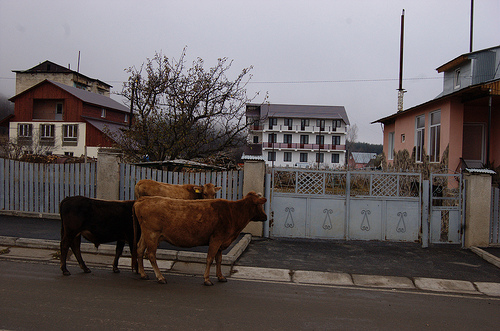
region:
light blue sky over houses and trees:
[2, 2, 492, 143]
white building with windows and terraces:
[240, 100, 345, 170]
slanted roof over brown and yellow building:
[0, 80, 130, 155]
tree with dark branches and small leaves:
[125, 50, 265, 160]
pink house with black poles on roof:
[351, 0, 483, 187]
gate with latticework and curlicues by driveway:
[265, 160, 415, 235]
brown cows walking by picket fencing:
[0, 150, 270, 285]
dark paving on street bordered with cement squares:
[5, 235, 495, 325]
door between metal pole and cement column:
[415, 162, 492, 247]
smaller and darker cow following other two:
[51, 173, 269, 283]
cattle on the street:
[53, 178, 271, 295]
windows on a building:
[281, 117, 296, 125]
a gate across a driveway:
[274, 165, 419, 254]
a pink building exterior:
[392, 121, 414, 132]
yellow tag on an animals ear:
[190, 184, 204, 193]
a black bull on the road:
[57, 193, 142, 268]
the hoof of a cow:
[201, 270, 216, 284]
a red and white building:
[12, 85, 119, 151]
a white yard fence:
[426, 173, 468, 248]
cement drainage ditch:
[282, 266, 465, 298]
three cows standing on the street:
[45, 158, 299, 295]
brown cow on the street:
[114, 189, 285, 291]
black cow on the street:
[38, 195, 138, 279]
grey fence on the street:
[255, 171, 416, 241]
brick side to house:
[7, 75, 88, 136]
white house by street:
[250, 102, 352, 174]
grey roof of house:
[252, 103, 343, 111]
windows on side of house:
[241, 122, 346, 179]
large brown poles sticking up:
[387, 11, 409, 111]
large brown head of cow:
[244, 185, 272, 222]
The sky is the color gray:
[58, 5, 399, 66]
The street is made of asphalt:
[33, 271, 449, 328]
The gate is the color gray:
[274, 169, 416, 238]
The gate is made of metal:
[273, 163, 423, 240]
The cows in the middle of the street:
[48, 171, 270, 287]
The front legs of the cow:
[198, 243, 231, 287]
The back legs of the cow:
[133, 230, 169, 284]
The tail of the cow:
[121, 193, 144, 270]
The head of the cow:
[243, 186, 270, 233]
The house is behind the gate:
[1, 48, 167, 166]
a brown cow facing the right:
[130, 190, 267, 284]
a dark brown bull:
[57, 195, 139, 277]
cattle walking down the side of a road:
[55, 182, 266, 284]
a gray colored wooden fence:
[0, 159, 241, 217]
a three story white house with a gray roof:
[244, 101, 349, 168]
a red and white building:
[9, 80, 129, 160]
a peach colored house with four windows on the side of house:
[378, 74, 499, 201]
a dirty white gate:
[266, 165, 466, 249]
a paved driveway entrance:
[227, 241, 497, 284]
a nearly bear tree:
[115, 40, 272, 165]